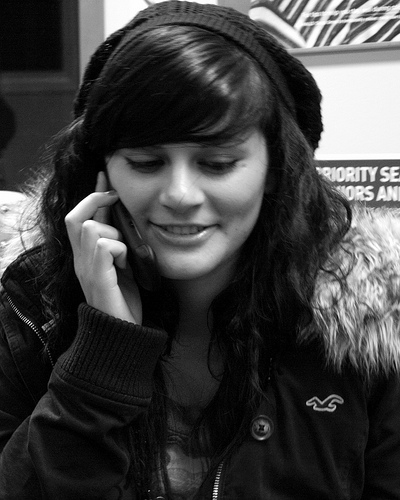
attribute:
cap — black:
[74, 0, 324, 154]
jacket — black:
[1, 240, 399, 499]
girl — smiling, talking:
[1, 21, 399, 497]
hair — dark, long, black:
[18, 23, 353, 404]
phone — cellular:
[112, 196, 160, 283]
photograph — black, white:
[2, 2, 399, 500]